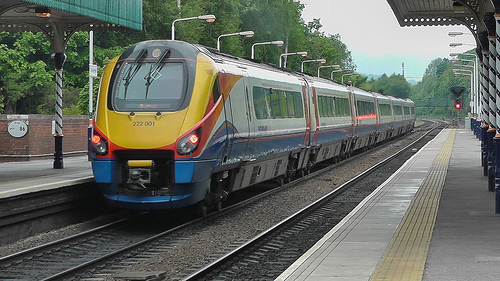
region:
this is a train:
[133, 29, 338, 189]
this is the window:
[247, 87, 272, 118]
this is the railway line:
[155, 233, 205, 278]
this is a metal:
[258, 222, 279, 239]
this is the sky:
[357, 29, 400, 67]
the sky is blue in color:
[381, 47, 401, 69]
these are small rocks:
[217, 214, 236, 239]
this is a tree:
[291, 17, 323, 36]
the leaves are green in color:
[284, 28, 316, 42]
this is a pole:
[84, 34, 99, 96]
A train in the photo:
[79, 20, 426, 216]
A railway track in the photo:
[112, 214, 264, 274]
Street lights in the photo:
[178, 10, 344, 72]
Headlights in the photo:
[80, 126, 207, 165]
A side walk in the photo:
[387, 174, 447, 279]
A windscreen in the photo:
[120, 62, 188, 112]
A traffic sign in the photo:
[445, 74, 467, 124]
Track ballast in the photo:
[242, 183, 334, 243]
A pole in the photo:
[47, 62, 75, 153]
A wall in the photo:
[10, 119, 47, 154]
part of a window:
[158, 74, 180, 93]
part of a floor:
[393, 215, 411, 245]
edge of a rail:
[271, 212, 303, 251]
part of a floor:
[444, 229, 463, 275]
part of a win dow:
[159, 70, 181, 98]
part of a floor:
[354, 227, 377, 272]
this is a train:
[79, 24, 440, 218]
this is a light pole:
[78, 25, 108, 109]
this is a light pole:
[157, 6, 217, 43]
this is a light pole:
[211, 15, 255, 55]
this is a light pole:
[249, 13, 281, 66]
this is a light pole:
[270, 40, 309, 68]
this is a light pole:
[300, 48, 329, 90]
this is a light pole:
[307, 58, 344, 95]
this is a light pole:
[332, 53, 357, 85]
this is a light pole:
[271, 24, 315, 77]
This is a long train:
[43, 66, 450, 248]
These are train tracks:
[34, 224, 139, 264]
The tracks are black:
[0, 203, 60, 256]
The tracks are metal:
[43, 217, 133, 279]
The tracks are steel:
[30, 231, 48, 273]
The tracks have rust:
[18, 221, 182, 273]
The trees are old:
[219, 0, 231, 26]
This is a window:
[80, 44, 227, 118]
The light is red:
[193, 132, 280, 157]